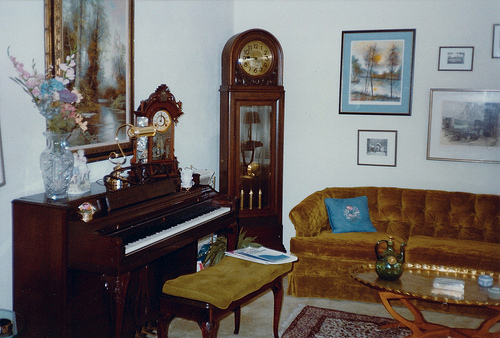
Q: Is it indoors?
A: Yes, it is indoors.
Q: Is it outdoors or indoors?
A: It is indoors.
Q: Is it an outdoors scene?
A: No, it is indoors.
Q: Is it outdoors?
A: No, it is indoors.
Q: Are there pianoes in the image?
A: Yes, there is a piano.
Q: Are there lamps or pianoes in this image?
A: Yes, there is a piano.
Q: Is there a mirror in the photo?
A: No, there are no mirrors.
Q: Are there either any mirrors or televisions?
A: No, there are no mirrors or televisions.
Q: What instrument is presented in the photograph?
A: The instrument is a piano.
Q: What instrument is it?
A: The instrument is a piano.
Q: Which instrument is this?
A: This is a piano.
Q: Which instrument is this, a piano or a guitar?
A: This is a piano.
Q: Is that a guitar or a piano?
A: That is a piano.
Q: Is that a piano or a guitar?
A: That is a piano.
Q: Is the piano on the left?
A: Yes, the piano is on the left of the image.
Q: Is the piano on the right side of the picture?
A: No, the piano is on the left of the image.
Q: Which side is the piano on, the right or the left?
A: The piano is on the left of the image.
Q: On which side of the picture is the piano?
A: The piano is on the left of the image.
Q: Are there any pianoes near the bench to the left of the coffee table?
A: Yes, there is a piano near the bench.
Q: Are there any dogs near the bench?
A: No, there is a piano near the bench.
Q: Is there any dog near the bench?
A: No, there is a piano near the bench.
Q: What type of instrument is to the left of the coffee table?
A: The instrument is a piano.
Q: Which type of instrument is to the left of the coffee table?
A: The instrument is a piano.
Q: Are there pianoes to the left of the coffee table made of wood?
A: Yes, there is a piano to the left of the coffee table.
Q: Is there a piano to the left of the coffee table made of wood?
A: Yes, there is a piano to the left of the coffee table.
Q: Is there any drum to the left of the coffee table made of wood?
A: No, there is a piano to the left of the coffee table.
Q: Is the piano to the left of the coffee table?
A: Yes, the piano is to the left of the coffee table.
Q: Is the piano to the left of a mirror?
A: No, the piano is to the left of the coffee table.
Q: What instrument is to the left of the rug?
A: The instrument is a piano.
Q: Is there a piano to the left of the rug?
A: Yes, there is a piano to the left of the rug.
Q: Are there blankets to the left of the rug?
A: No, there is a piano to the left of the rug.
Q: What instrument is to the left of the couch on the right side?
A: The instrument is a piano.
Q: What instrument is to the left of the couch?
A: The instrument is a piano.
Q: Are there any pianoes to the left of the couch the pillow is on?
A: Yes, there is a piano to the left of the couch.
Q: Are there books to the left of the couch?
A: No, there is a piano to the left of the couch.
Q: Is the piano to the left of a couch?
A: Yes, the piano is to the left of a couch.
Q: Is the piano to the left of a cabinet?
A: No, the piano is to the left of a couch.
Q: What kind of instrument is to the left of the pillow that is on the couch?
A: The instrument is a piano.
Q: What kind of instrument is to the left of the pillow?
A: The instrument is a piano.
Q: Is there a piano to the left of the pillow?
A: Yes, there is a piano to the left of the pillow.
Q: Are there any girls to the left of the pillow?
A: No, there is a piano to the left of the pillow.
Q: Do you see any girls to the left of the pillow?
A: No, there is a piano to the left of the pillow.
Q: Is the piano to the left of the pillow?
A: Yes, the piano is to the left of the pillow.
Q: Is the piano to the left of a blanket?
A: No, the piano is to the left of the pillow.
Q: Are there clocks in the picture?
A: Yes, there is a clock.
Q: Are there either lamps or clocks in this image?
A: Yes, there is a clock.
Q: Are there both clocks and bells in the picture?
A: No, there is a clock but no bells.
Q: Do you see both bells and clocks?
A: No, there is a clock but no bells.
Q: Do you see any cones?
A: No, there are no cones.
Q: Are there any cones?
A: No, there are no cones.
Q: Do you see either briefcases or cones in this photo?
A: No, there are no cones or briefcases.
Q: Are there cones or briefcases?
A: No, there are no cones or briefcases.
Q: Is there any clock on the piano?
A: Yes, there is a clock on the piano.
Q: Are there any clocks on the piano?
A: Yes, there is a clock on the piano.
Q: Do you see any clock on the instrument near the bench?
A: Yes, there is a clock on the piano.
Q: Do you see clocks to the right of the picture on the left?
A: Yes, there is a clock to the right of the picture.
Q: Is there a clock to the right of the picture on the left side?
A: Yes, there is a clock to the right of the picture.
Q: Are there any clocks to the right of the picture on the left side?
A: Yes, there is a clock to the right of the picture.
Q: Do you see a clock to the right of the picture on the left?
A: Yes, there is a clock to the right of the picture.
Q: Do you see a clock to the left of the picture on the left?
A: No, the clock is to the right of the picture.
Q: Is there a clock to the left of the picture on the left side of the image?
A: No, the clock is to the right of the picture.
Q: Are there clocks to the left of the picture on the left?
A: No, the clock is to the right of the picture.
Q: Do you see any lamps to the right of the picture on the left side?
A: No, there is a clock to the right of the picture.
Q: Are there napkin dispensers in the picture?
A: No, there are no napkin dispensers.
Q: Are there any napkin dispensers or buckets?
A: No, there are no napkin dispensers or buckets.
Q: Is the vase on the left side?
A: Yes, the vase is on the left of the image.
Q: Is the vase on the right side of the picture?
A: No, the vase is on the left of the image.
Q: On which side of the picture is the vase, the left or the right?
A: The vase is on the left of the image.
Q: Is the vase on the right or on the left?
A: The vase is on the left of the image.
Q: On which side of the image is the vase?
A: The vase is on the left of the image.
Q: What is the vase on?
A: The vase is on the piano.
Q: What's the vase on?
A: The vase is on the piano.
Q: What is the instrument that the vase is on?
A: The instrument is a piano.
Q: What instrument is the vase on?
A: The vase is on the piano.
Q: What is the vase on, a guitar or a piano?
A: The vase is on a piano.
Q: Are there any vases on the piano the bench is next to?
A: Yes, there is a vase on the piano.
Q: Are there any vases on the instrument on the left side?
A: Yes, there is a vase on the piano.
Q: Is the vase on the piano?
A: Yes, the vase is on the piano.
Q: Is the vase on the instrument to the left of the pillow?
A: Yes, the vase is on the piano.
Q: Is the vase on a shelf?
A: No, the vase is on the piano.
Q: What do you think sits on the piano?
A: The vase sits on the piano.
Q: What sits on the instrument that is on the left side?
A: The vase sits on the piano.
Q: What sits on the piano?
A: The vase sits on the piano.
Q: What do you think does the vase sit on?
A: The vase sits on the piano.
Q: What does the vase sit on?
A: The vase sits on the piano.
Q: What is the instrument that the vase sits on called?
A: The instrument is a piano.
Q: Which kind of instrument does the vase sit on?
A: The vase sits on the piano.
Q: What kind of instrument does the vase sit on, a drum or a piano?
A: The vase sits on a piano.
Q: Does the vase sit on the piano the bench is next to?
A: Yes, the vase sits on the piano.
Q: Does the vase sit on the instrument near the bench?
A: Yes, the vase sits on the piano.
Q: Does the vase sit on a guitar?
A: No, the vase sits on the piano.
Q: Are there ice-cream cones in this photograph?
A: No, there are no ice-cream cones.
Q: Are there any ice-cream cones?
A: No, there are no ice-cream cones.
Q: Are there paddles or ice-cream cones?
A: No, there are no ice-cream cones or paddles.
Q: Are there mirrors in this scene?
A: No, there are no mirrors.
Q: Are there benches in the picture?
A: Yes, there is a bench.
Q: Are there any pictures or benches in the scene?
A: Yes, there is a bench.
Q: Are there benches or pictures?
A: Yes, there is a bench.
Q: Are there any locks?
A: No, there are no locks.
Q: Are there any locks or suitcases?
A: No, there are no locks or suitcases.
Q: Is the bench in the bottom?
A: Yes, the bench is in the bottom of the image.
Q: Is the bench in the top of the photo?
A: No, the bench is in the bottom of the image.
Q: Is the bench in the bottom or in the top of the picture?
A: The bench is in the bottom of the image.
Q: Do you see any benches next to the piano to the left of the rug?
A: Yes, there is a bench next to the piano.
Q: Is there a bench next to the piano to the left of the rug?
A: Yes, there is a bench next to the piano.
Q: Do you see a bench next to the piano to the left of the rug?
A: Yes, there is a bench next to the piano.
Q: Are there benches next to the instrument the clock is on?
A: Yes, there is a bench next to the piano.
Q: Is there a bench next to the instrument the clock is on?
A: Yes, there is a bench next to the piano.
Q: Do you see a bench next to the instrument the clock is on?
A: Yes, there is a bench next to the piano.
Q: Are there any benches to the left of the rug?
A: Yes, there is a bench to the left of the rug.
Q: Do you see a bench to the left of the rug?
A: Yes, there is a bench to the left of the rug.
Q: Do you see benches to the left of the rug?
A: Yes, there is a bench to the left of the rug.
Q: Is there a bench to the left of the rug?
A: Yes, there is a bench to the left of the rug.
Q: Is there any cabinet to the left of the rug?
A: No, there is a bench to the left of the rug.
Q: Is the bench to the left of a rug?
A: Yes, the bench is to the left of a rug.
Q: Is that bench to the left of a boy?
A: No, the bench is to the left of a rug.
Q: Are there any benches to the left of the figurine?
A: Yes, there is a bench to the left of the figurine.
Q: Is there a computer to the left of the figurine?
A: No, there is a bench to the left of the figurine.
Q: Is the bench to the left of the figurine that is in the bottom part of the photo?
A: Yes, the bench is to the left of the figurine.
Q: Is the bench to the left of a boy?
A: No, the bench is to the left of the figurine.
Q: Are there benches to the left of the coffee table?
A: Yes, there is a bench to the left of the coffee table.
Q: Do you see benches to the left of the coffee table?
A: Yes, there is a bench to the left of the coffee table.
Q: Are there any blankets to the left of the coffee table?
A: No, there is a bench to the left of the coffee table.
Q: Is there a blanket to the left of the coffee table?
A: No, there is a bench to the left of the coffee table.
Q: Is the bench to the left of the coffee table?
A: Yes, the bench is to the left of the coffee table.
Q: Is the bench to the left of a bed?
A: No, the bench is to the left of the coffee table.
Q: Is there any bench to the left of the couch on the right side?
A: Yes, there is a bench to the left of the couch.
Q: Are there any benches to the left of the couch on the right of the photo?
A: Yes, there is a bench to the left of the couch.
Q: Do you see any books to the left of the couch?
A: No, there is a bench to the left of the couch.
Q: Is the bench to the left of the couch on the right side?
A: Yes, the bench is to the left of the couch.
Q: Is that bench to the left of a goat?
A: No, the bench is to the left of the couch.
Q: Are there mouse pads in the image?
A: No, there are no mouse pads.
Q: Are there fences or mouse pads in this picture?
A: No, there are no mouse pads or fences.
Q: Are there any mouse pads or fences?
A: No, there are no mouse pads or fences.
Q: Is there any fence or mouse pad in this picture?
A: No, there are no mouse pads or fences.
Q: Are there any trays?
A: No, there are no trays.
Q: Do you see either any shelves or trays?
A: No, there are no trays or shelves.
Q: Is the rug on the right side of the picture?
A: Yes, the rug is on the right of the image.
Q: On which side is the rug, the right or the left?
A: The rug is on the right of the image.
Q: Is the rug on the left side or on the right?
A: The rug is on the right of the image.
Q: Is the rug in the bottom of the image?
A: Yes, the rug is in the bottom of the image.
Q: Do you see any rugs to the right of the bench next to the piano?
A: Yes, there is a rug to the right of the bench.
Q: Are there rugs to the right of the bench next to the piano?
A: Yes, there is a rug to the right of the bench.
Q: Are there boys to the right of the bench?
A: No, there is a rug to the right of the bench.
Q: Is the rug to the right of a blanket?
A: No, the rug is to the right of the bench.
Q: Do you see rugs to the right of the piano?
A: Yes, there is a rug to the right of the piano.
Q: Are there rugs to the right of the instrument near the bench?
A: Yes, there is a rug to the right of the piano.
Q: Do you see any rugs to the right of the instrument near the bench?
A: Yes, there is a rug to the right of the piano.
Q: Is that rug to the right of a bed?
A: No, the rug is to the right of a piano.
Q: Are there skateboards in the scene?
A: No, there are no skateboards.